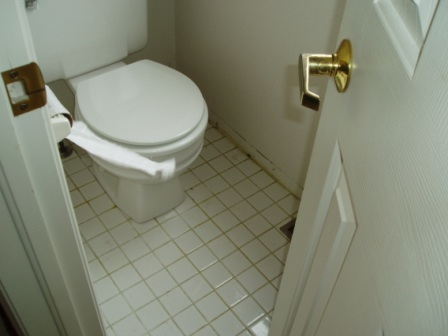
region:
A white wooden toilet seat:
[74, 55, 207, 147]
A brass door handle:
[296, 36, 355, 113]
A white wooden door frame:
[0, 0, 108, 335]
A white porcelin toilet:
[19, 0, 211, 226]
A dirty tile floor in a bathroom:
[59, 118, 302, 335]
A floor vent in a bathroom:
[277, 213, 298, 241]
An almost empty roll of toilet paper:
[38, 80, 74, 130]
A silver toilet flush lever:
[23, 0, 39, 13]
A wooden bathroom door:
[265, 0, 446, 335]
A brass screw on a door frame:
[15, 99, 28, 113]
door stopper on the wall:
[4, 68, 46, 115]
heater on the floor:
[279, 219, 295, 239]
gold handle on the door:
[291, 34, 356, 117]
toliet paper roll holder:
[49, 93, 73, 143]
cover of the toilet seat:
[71, 54, 207, 148]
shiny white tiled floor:
[177, 256, 267, 330]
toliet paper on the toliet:
[90, 143, 140, 167]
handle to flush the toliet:
[24, 1, 41, 10]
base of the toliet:
[124, 187, 179, 224]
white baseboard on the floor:
[224, 120, 259, 157]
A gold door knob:
[295, 36, 357, 109]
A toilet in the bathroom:
[17, 2, 216, 225]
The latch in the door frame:
[2, 60, 48, 122]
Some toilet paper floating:
[69, 113, 182, 188]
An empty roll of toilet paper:
[37, 79, 76, 130]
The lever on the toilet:
[19, 1, 40, 12]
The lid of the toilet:
[75, 56, 205, 147]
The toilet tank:
[16, 0, 151, 83]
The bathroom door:
[267, 1, 446, 335]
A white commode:
[2, 0, 215, 225]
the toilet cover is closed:
[66, 57, 222, 202]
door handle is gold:
[269, 44, 379, 115]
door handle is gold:
[283, 19, 392, 137]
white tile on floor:
[231, 228, 250, 245]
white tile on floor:
[163, 292, 184, 308]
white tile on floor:
[218, 285, 247, 306]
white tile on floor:
[235, 266, 265, 285]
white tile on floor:
[107, 249, 126, 271]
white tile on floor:
[180, 236, 195, 252]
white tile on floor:
[166, 215, 190, 238]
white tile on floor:
[235, 299, 261, 329]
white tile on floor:
[171, 303, 199, 331]